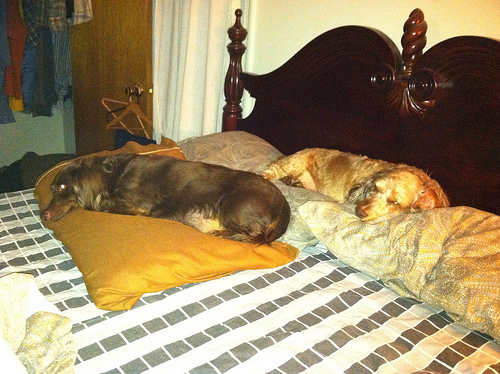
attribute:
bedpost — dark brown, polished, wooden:
[220, 6, 248, 132]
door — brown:
[63, 4, 160, 149]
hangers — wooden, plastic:
[99, 96, 155, 137]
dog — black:
[41, 150, 288, 243]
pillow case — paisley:
[168, 127, 330, 242]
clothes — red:
[6, 3, 30, 113]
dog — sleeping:
[33, 140, 301, 257]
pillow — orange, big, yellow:
[37, 133, 305, 333]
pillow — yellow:
[187, 113, 354, 267]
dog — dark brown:
[52, 137, 287, 253]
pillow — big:
[180, 118, 499, 339]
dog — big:
[256, 142, 448, 232]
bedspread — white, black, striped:
[1, 185, 498, 372]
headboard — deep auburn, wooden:
[219, 7, 499, 206]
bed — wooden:
[12, 187, 489, 368]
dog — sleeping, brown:
[258, 147, 448, 222]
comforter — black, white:
[3, 180, 498, 370]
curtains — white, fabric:
[159, 0, 224, 133]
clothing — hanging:
[3, 7, 74, 125]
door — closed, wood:
[64, 2, 161, 170]